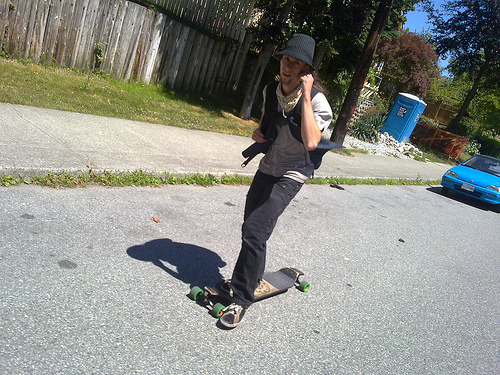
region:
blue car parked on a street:
[437, 147, 499, 222]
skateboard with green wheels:
[183, 255, 315, 324]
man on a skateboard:
[217, 23, 330, 333]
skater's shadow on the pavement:
[123, 227, 236, 311]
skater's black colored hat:
[271, 30, 320, 73]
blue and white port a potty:
[376, 85, 426, 152]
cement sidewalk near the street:
[2, 98, 461, 186]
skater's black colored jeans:
[227, 167, 306, 312]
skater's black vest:
[239, 68, 346, 181]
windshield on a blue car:
[461, 151, 499, 178]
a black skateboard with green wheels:
[185, 263, 309, 322]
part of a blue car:
[440, 153, 498, 215]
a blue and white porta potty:
[381, 87, 428, 149]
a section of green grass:
[0, 45, 254, 134]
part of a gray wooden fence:
[0, 0, 251, 100]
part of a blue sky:
[407, 10, 428, 31]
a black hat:
[273, 31, 322, 66]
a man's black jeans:
[230, 171, 301, 302]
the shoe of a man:
[217, 303, 246, 329]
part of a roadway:
[0, 185, 499, 374]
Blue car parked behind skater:
[429, 145, 497, 233]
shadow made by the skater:
[121, 230, 243, 310]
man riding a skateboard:
[184, 29, 335, 341]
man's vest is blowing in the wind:
[246, 74, 350, 171]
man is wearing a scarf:
[269, 74, 312, 117]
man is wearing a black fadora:
[262, 18, 322, 75]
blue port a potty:
[373, 86, 429, 154]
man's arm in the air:
[293, 67, 332, 155]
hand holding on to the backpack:
[246, 115, 274, 159]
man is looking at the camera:
[264, 26, 319, 101]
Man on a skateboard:
[188, 30, 334, 329]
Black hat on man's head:
[273, 32, 319, 68]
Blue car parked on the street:
[438, 151, 498, 206]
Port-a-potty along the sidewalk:
[378, 89, 429, 149]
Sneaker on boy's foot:
[218, 295, 248, 328]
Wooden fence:
[0, 3, 272, 109]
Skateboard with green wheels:
[186, 266, 312, 318]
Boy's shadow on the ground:
[124, 233, 229, 281]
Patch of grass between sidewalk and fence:
[0, 53, 259, 135]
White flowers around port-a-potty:
[375, 131, 431, 161]